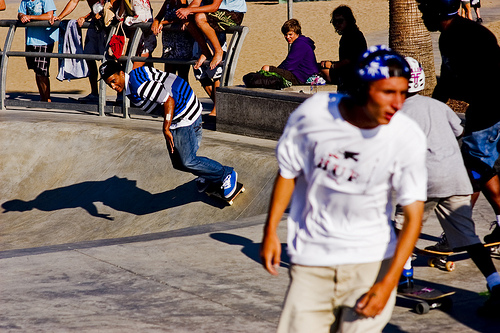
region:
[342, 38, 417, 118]
Man wearing a hat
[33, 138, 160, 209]
Shadow on the pavement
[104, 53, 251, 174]
Man wearing a striped shirt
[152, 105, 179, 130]
Bandaid on man's arm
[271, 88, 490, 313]
Man wearing a tshirt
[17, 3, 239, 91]
People sitting on the railing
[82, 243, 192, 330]
Crack in the pavement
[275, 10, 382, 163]
People sitting on the wall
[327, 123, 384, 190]
Arrow on man's shirt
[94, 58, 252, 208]
Man on a skateboard in a bowl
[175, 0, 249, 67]
Person sitting on a handrail watching skaters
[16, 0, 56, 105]
Person leaning on a handrail watching skaters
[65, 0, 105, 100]
Person leaning on a handrail watching skaters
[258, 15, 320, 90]
Person in purple sweatshirt watching skaters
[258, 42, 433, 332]
Guy skateboarding with white shirt and blue hat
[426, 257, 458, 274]
Front wheels on a rolling skateboard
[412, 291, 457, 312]
Back wheels on a rolling skateboard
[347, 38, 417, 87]
Blue snapback hat on a skateboarder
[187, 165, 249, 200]
Man wearing shoes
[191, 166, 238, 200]
Man is wearing shoes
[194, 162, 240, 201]
Man wearing blue and white shoes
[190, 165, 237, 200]
Man is wearing blue and white shoes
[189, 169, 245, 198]
Man on a skateboard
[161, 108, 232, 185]
Man is wearing pants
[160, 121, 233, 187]
Man wearing pants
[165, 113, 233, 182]
Man is wearing blue jeans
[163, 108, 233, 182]
Man wearing blue jeans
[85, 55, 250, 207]
Young man on skate board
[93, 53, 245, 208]
Young man in hat on skate board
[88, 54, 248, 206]
Young man in hat wearing blue on skate board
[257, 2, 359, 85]
Girl with her shadow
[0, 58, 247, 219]
Boy on skate board with shadow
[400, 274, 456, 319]
Front of a skate board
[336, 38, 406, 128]
Young man wearing hat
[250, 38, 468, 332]
Young man wearing hat, white tshirt and khaki pants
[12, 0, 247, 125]
Kids sitting and leaning on a railing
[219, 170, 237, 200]
blue and white skate shoes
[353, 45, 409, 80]
blue design on the hat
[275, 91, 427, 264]
white tee shirt with a black logo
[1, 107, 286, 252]
concrete skateboard bowl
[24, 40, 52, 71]
black and white shorts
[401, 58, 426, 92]
a white safety helmet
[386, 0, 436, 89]
a trunk of a palm tree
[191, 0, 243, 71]
someone sitting on the metal railing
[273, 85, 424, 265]
man wearing a white tee shirt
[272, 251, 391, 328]
man wearing white pants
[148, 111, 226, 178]
man wearing blue jeans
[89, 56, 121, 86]
man wearing a black hat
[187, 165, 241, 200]
man wearing blue sneakers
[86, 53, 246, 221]
man riding a skateboard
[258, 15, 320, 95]
woman sitting on the ground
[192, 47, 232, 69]
person feet on the rail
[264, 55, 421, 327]
A person is playing.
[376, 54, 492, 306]
A person is playing.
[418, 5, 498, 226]
A person is playing.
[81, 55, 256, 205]
A person is playing.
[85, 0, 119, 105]
A person is standing up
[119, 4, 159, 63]
A person is standing up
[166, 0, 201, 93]
A person is standing up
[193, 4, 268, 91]
A person is sitting down